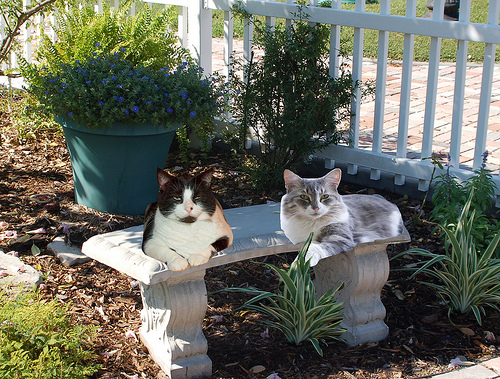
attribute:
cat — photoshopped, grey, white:
[278, 169, 402, 267]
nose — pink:
[185, 207, 192, 213]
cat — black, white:
[142, 167, 234, 272]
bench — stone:
[81, 194, 413, 377]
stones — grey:
[1, 237, 91, 286]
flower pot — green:
[55, 117, 184, 215]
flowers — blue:
[48, 41, 202, 122]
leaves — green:
[0, 286, 103, 378]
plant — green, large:
[14, 2, 220, 162]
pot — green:
[52, 114, 185, 215]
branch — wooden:
[0, 0, 56, 78]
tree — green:
[224, 0, 375, 187]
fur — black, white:
[141, 167, 234, 273]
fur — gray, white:
[280, 167, 404, 268]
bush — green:
[1, 287, 105, 377]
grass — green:
[81, 1, 499, 63]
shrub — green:
[433, 150, 496, 243]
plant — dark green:
[216, 1, 375, 186]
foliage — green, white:
[207, 232, 349, 359]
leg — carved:
[137, 269, 212, 377]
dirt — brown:
[1, 85, 498, 379]